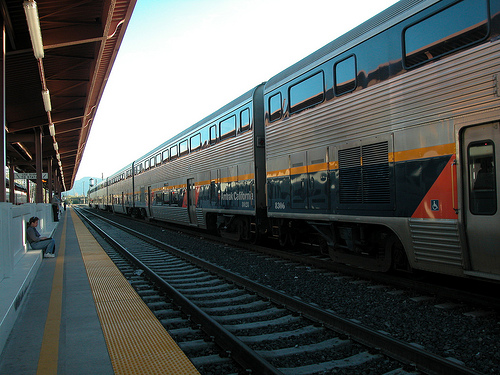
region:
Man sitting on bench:
[20, 215, 61, 271]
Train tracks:
[65, 187, 463, 367]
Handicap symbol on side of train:
[421, 195, 439, 212]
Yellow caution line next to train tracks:
[62, 182, 205, 371]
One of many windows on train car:
[286, 79, 327, 105]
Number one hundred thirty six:
[268, 197, 293, 215]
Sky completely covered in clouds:
[71, 18, 358, 215]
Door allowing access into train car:
[457, 112, 496, 279]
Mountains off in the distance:
[73, 172, 94, 196]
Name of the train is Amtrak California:
[214, 186, 260, 212]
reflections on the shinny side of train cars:
[189, 169, 323, 209]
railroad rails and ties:
[110, 230, 244, 328]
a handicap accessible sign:
[428, 195, 441, 213]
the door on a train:
[458, 127, 498, 270]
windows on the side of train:
[265, 55, 362, 105]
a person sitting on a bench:
[17, 210, 57, 270]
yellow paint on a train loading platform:
[45, 253, 136, 359]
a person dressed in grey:
[22, 223, 59, 255]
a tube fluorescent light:
[22, 0, 52, 62]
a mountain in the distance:
[70, 171, 105, 204]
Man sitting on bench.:
[22, 216, 58, 263]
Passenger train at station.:
[90, 1, 497, 279]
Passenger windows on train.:
[110, 47, 498, 180]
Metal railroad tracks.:
[145, 253, 412, 373]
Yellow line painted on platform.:
[39, 209, 71, 374]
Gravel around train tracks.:
[131, 240, 448, 372]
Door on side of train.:
[453, 112, 498, 283]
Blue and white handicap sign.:
[427, 199, 441, 214]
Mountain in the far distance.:
[55, 165, 105, 210]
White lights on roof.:
[18, 0, 75, 200]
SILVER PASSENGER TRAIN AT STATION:
[127, 84, 480, 293]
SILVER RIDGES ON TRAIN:
[367, 66, 463, 108]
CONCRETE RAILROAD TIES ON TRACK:
[138, 229, 269, 364]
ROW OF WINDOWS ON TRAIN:
[277, 69, 417, 149]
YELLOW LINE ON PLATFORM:
[59, 216, 63, 373]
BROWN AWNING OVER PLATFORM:
[11, 30, 116, 148]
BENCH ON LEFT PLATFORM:
[5, 203, 65, 243]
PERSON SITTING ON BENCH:
[29, 226, 70, 258]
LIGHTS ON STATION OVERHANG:
[24, 82, 66, 112]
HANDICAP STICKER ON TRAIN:
[422, 194, 448, 206]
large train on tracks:
[88, 0, 498, 289]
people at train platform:
[26, 191, 68, 260]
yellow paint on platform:
[41, 204, 196, 374]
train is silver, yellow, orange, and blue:
[88, 57, 498, 285]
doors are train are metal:
[98, 121, 499, 281]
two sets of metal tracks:
[73, 201, 498, 373]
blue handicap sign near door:
[427, 199, 442, 213]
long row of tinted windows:
[83, 3, 497, 193]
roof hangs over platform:
[1, 0, 138, 190]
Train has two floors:
[86, 0, 498, 285]